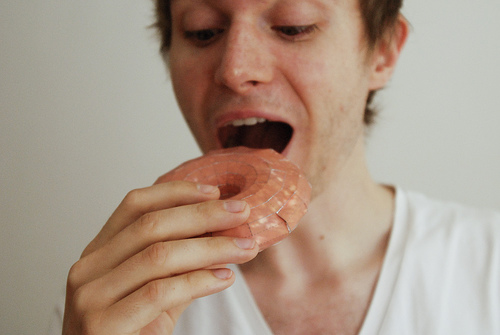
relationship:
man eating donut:
[63, 0, 500, 334] [153, 147, 313, 252]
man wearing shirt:
[63, 0, 500, 334] [170, 184, 500, 334]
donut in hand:
[153, 147, 313, 252] [61, 182, 261, 333]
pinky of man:
[112, 269, 234, 334] [63, 0, 500, 334]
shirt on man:
[170, 184, 500, 334] [63, 0, 500, 334]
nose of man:
[214, 10, 274, 95] [63, 0, 500, 334]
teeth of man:
[224, 117, 269, 127] [63, 0, 500, 334]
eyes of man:
[187, 24, 317, 41] [63, 0, 500, 334]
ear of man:
[367, 13, 408, 88] [63, 0, 500, 334]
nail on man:
[196, 184, 219, 194] [63, 0, 500, 334]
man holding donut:
[63, 0, 500, 334] [153, 147, 313, 252]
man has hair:
[63, 0, 500, 334] [150, 0, 402, 129]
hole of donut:
[219, 181, 241, 198] [153, 147, 313, 252]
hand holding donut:
[61, 182, 261, 333] [153, 147, 313, 252]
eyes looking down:
[187, 24, 317, 41] [1, 326, 499, 334]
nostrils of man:
[217, 82, 261, 93] [63, 0, 500, 334]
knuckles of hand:
[67, 263, 105, 335] [61, 182, 261, 333]